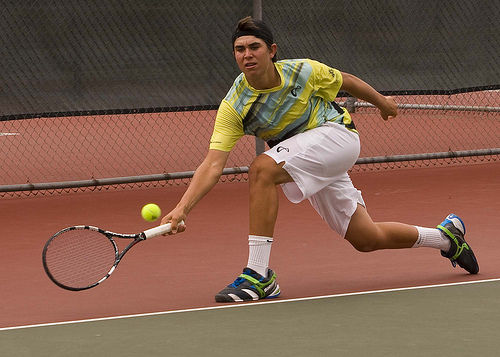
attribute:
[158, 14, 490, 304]
man — playing tennis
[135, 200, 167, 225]
tennis ball — yellow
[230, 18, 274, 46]
cap — is black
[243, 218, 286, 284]
sock — is white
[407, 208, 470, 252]
sock — is white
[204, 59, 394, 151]
shirt — short sleeved 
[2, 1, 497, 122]
tarp — black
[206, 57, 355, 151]
shirt — yellow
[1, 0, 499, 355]
court — green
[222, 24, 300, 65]
cap — backwards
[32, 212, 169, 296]
tennis racket — partly white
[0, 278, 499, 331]
line — white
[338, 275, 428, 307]
ground — concrete 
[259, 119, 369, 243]
shorts — white